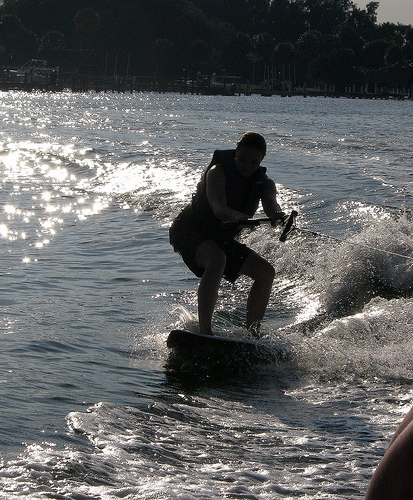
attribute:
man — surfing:
[171, 135, 299, 342]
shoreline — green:
[2, 3, 403, 66]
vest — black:
[188, 150, 283, 228]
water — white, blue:
[19, 88, 167, 304]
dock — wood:
[1, 53, 393, 98]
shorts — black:
[170, 208, 252, 278]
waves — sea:
[16, 131, 182, 247]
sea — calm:
[50, 249, 132, 373]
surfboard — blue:
[154, 325, 288, 363]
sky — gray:
[370, 0, 409, 26]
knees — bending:
[201, 251, 278, 281]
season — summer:
[12, 7, 389, 421]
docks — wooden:
[23, 67, 389, 92]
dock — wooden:
[5, 73, 411, 100]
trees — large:
[4, 1, 400, 82]